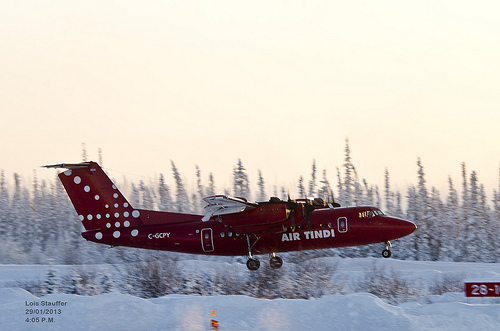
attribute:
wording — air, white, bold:
[281, 231, 337, 240]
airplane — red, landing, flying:
[42, 162, 417, 269]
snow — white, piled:
[11, 287, 500, 330]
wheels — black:
[247, 255, 258, 272]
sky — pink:
[1, 4, 497, 212]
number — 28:
[471, 285, 489, 297]